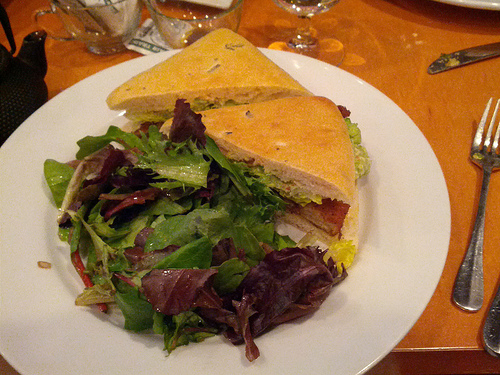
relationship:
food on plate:
[47, 26, 371, 366] [4, 47, 449, 368]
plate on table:
[4, 47, 449, 368] [2, 0, 499, 353]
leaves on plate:
[43, 118, 303, 342] [4, 47, 449, 368]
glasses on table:
[151, 1, 348, 54] [2, 39, 474, 333]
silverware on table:
[451, 59, 498, 317] [26, 18, 480, 368]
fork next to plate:
[445, 92, 483, 315] [4, 47, 449, 368]